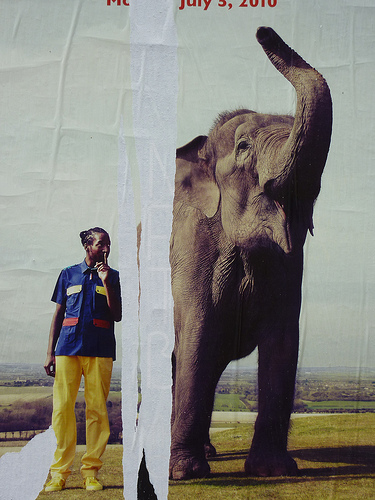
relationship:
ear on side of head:
[174, 133, 219, 218] [177, 107, 328, 255]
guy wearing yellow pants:
[42, 227, 122, 494] [47, 351, 112, 482]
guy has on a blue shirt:
[42, 227, 122, 494] [62, 266, 109, 345]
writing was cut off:
[176, 38, 278, 39] [160, 74, 180, 78]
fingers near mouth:
[92, 248, 111, 283] [96, 250, 113, 258]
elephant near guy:
[136, 25, 333, 482] [28, 224, 124, 495]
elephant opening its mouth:
[157, 17, 341, 464] [268, 191, 315, 255]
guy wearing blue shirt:
[42, 227, 122, 494] [50, 257, 122, 362]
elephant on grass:
[136, 25, 333, 482] [176, 419, 339, 496]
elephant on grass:
[136, 25, 333, 482] [304, 399, 362, 407]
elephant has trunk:
[136, 25, 333, 482] [255, 25, 334, 205]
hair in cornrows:
[81, 224, 114, 258] [79, 225, 101, 239]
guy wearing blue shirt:
[42, 227, 123, 497] [47, 262, 119, 363]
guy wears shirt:
[42, 227, 123, 497] [44, 258, 125, 365]